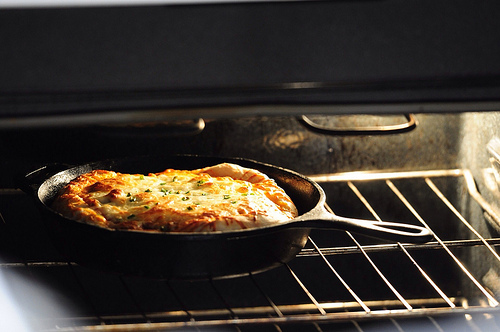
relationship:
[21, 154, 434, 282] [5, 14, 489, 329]
black pan in oven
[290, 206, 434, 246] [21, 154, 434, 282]
handle on black pan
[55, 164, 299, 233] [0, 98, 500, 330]
pizza on oven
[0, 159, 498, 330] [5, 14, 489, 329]
rack on oven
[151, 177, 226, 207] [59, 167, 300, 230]
green onion on pizza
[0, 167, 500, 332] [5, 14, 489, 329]
rack on oven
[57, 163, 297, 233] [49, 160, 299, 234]
cheese over bread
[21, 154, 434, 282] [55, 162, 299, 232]
black pan of bread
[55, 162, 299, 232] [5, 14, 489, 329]
bread in oven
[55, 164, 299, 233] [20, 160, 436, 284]
pizza in pan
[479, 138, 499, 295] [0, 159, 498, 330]
grooves on rack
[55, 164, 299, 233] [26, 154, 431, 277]
pizza on skillet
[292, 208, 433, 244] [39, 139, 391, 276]
handle of pan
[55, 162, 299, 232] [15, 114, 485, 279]
bread in pan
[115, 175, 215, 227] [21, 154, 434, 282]
garnish on black pan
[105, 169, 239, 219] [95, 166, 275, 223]
spices on cheese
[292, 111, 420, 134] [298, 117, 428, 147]
element for broiler